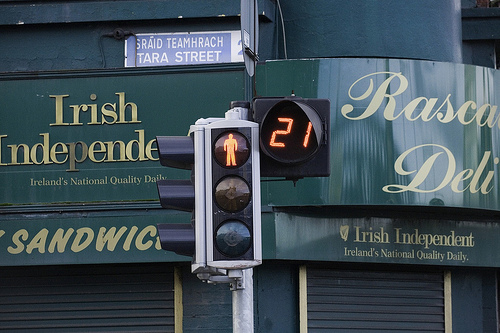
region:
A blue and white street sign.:
[123, 31, 248, 67]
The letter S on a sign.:
[5, 226, 30, 255]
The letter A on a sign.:
[25, 223, 50, 254]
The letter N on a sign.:
[47, 225, 74, 255]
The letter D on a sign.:
[69, 225, 95, 254]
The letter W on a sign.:
[93, 224, 128, 254]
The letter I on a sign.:
[121, 222, 138, 253]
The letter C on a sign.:
[133, 221, 158, 253]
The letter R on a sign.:
[65, 100, 89, 126]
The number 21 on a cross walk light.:
[267, 113, 315, 150]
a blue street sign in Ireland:
[124, 30, 240, 66]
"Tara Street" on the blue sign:
[135, 50, 225, 65]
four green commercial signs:
[0, 57, 498, 267]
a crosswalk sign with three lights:
[186, 117, 261, 280]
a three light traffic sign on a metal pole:
[151, 132, 191, 252]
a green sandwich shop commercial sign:
[0, 210, 155, 265]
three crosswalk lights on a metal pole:
[211, 127, 251, 257]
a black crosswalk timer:
[255, 90, 330, 186]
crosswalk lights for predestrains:
[203, 122, 260, 269]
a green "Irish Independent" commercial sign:
[261, 213, 497, 265]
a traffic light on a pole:
[137, 52, 311, 271]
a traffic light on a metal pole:
[157, 108, 290, 328]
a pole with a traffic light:
[161, 125, 308, 332]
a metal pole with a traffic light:
[152, 118, 278, 317]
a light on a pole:
[161, 96, 304, 328]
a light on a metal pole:
[144, 108, 255, 328]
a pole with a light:
[171, 113, 316, 326]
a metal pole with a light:
[144, 115, 274, 332]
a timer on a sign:
[223, 81, 371, 206]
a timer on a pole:
[196, 80, 411, 278]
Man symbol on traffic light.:
[203, 115, 260, 173]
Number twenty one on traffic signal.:
[255, 98, 328, 188]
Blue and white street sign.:
[100, 13, 261, 80]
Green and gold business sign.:
[2, 78, 229, 209]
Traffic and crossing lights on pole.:
[145, 100, 332, 329]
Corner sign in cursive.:
[260, 1, 499, 289]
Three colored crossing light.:
[185, 100, 278, 298]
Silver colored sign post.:
[178, 95, 264, 330]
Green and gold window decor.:
[0, 268, 231, 330]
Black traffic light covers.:
[137, 97, 272, 292]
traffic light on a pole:
[145, 108, 290, 275]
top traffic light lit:
[203, 133, 254, 165]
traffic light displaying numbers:
[259, 94, 326, 178]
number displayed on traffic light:
[274, 111, 304, 150]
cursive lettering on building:
[345, 69, 499, 198]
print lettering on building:
[339, 210, 484, 266]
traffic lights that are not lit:
[213, 175, 254, 260]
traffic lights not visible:
[142, 135, 201, 250]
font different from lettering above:
[3, 219, 158, 254]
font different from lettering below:
[8, 93, 181, 193]